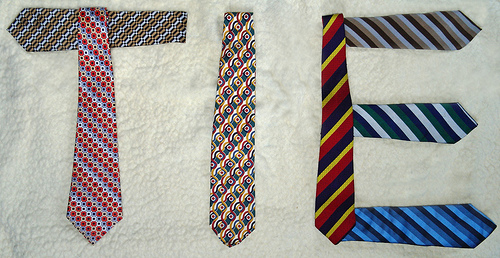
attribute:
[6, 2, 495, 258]
blanket — cotton, white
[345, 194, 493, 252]
tie — blue, on side, horizontal, striped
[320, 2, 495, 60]
tie — brown, blue, green, striped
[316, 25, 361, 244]
tie — yellow, gold, red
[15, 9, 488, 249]
letters — spelling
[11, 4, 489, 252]
ties — several, spelling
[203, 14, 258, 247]
tie — standing, paisly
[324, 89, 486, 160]
tie — middle, striped, green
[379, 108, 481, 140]
stripes — green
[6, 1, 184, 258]
sign — t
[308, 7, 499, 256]
letter — e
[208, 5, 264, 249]
letter — i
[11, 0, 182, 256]
letter — t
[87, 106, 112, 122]
circles — red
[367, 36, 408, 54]
strips — black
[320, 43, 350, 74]
strips — yellow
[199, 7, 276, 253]
tie — purple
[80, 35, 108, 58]
polkadot — white